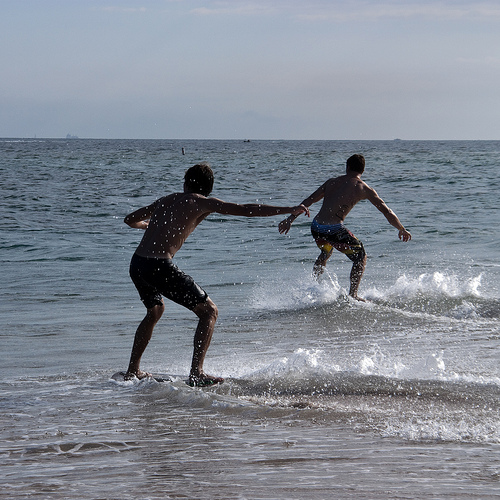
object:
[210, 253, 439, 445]
waves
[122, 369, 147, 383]
foot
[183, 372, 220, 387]
foot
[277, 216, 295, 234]
hand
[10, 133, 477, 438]
water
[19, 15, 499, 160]
sky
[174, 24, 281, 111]
clouds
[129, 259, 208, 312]
shorts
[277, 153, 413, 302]
person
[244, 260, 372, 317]
water splash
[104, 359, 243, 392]
surfboard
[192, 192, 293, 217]
arms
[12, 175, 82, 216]
line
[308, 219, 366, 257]
shorts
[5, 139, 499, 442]
ocean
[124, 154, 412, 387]
couple people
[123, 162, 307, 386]
male people